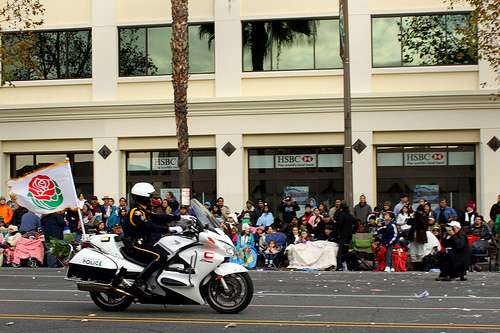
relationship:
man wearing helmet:
[119, 180, 197, 300] [130, 181, 157, 206]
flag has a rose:
[7, 157, 88, 240] [27, 174, 57, 201]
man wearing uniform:
[119, 180, 197, 300] [120, 207, 197, 295]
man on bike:
[119, 180, 197, 300] [66, 197, 255, 312]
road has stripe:
[1, 266, 498, 332] [4, 312, 500, 330]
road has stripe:
[1, 266, 498, 332] [0, 287, 500, 301]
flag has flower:
[7, 157, 88, 240] [27, 174, 57, 201]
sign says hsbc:
[273, 152, 318, 168] [278, 154, 300, 163]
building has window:
[1, 3, 499, 230] [239, 15, 346, 75]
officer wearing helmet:
[119, 180, 197, 300] [130, 181, 157, 206]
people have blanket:
[206, 194, 499, 271] [286, 240, 337, 273]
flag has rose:
[7, 157, 88, 240] [27, 174, 57, 201]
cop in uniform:
[119, 180, 197, 300] [120, 207, 197, 295]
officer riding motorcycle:
[119, 180, 197, 300] [66, 197, 255, 312]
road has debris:
[1, 266, 498, 332] [414, 287, 449, 301]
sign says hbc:
[273, 152, 318, 168] [278, 154, 300, 163]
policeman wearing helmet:
[119, 180, 197, 300] [130, 181, 157, 206]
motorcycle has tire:
[66, 197, 255, 312] [203, 268, 255, 316]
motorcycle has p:
[66, 197, 255, 312] [80, 255, 87, 265]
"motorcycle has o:
[66, 197, 255, 312] [85, 259, 92, 266]